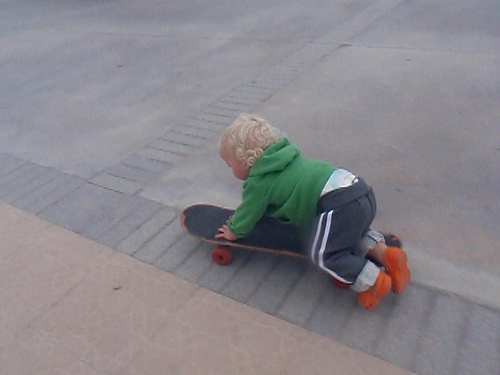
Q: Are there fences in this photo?
A: No, there are no fences.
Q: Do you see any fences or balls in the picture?
A: No, there are no fences or balls.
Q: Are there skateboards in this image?
A: Yes, there is a skateboard.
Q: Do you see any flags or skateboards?
A: Yes, there is a skateboard.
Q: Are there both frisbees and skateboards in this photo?
A: No, there is a skateboard but no frisbees.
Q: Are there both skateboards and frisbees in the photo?
A: No, there is a skateboard but no frisbees.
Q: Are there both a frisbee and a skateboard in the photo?
A: No, there is a skateboard but no frisbees.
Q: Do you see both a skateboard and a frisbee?
A: No, there is a skateboard but no frisbees.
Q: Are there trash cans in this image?
A: No, there are no trash cans.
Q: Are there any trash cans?
A: No, there are no trash cans.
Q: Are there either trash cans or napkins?
A: No, there are no trash cans or napkins.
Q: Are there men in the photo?
A: No, there are no men.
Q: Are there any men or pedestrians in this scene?
A: No, there are no men or pedestrians.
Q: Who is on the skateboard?
A: The boy is on the skateboard.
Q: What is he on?
A: The boy is on the skateboard.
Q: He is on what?
A: The boy is on the skateboard.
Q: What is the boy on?
A: The boy is on the skateboard.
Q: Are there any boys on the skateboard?
A: Yes, there is a boy on the skateboard.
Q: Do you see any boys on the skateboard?
A: Yes, there is a boy on the skateboard.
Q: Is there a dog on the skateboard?
A: No, there is a boy on the skateboard.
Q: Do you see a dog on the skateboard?
A: No, there is a boy on the skateboard.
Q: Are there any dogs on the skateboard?
A: No, there is a boy on the skateboard.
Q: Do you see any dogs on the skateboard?
A: No, there is a boy on the skateboard.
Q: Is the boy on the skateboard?
A: Yes, the boy is on the skateboard.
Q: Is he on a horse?
A: No, the boy is on the skateboard.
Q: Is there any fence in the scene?
A: No, there are no fences.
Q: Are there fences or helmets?
A: No, there are no fences or helmets.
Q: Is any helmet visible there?
A: No, there are no helmets.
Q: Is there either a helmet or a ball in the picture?
A: No, there are no helmets or balls.